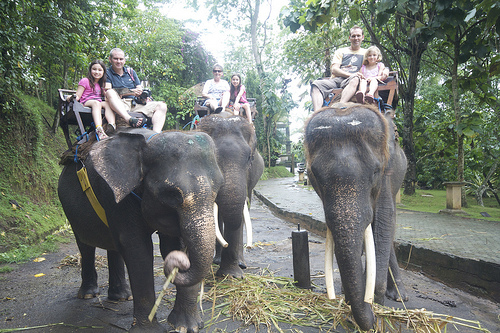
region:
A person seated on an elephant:
[75, 56, 109, 128]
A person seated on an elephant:
[97, 48, 168, 130]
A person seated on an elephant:
[197, 52, 232, 110]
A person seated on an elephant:
[231, 74, 257, 129]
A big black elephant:
[18, 106, 214, 313]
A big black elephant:
[302, 93, 407, 319]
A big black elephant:
[200, 113, 279, 273]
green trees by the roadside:
[375, 0, 498, 170]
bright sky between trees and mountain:
[152, 5, 327, 171]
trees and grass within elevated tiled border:
[260, 10, 495, 270]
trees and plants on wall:
[5, 5, 290, 251]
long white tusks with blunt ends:
[317, 215, 377, 305]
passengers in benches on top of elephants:
[55, 21, 407, 321]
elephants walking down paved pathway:
[17, 17, 482, 327]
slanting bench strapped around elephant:
[51, 41, 166, 226]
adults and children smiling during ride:
[197, 21, 394, 308]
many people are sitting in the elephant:
[36, 12, 446, 329]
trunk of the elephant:
[174, 217, 211, 300]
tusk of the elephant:
[361, 227, 381, 308]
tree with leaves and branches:
[245, 36, 285, 161]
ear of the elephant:
[91, 128, 148, 201]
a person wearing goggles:
[208, 65, 222, 75]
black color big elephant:
[303, 105, 413, 307]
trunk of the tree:
[401, 53, 421, 168]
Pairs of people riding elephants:
[42, 28, 429, 330]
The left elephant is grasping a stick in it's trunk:
[143, 246, 228, 323]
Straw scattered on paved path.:
[201, 271, 473, 332]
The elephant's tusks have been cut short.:
[318, 222, 382, 309]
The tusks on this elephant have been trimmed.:
[207, 197, 259, 253]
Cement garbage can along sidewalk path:
[441, 176, 464, 211]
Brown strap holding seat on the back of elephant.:
[68, 153, 115, 229]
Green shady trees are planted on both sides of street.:
[1, 1, 498, 196]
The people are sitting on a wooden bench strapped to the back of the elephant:
[52, 45, 167, 144]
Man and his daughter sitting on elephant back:
[308, 23, 404, 118]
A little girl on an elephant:
[365, 45, 388, 91]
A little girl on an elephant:
[229, 71, 256, 108]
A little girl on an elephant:
[72, 59, 104, 137]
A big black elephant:
[199, 123, 283, 278]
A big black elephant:
[40, 149, 235, 323]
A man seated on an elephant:
[337, 4, 362, 95]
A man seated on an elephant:
[195, 56, 225, 111]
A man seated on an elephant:
[111, 45, 173, 112]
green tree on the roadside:
[395, 1, 472, 166]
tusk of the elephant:
[353, 220, 386, 302]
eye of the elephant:
[367, 152, 384, 183]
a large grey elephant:
[288, 98, 430, 325]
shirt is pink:
[77, 78, 103, 104]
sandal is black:
[130, 114, 150, 132]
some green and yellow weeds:
[211, 259, 384, 331]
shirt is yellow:
[328, 50, 378, 83]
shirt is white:
[201, 80, 236, 99]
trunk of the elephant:
[137, 210, 234, 299]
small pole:
[286, 221, 315, 293]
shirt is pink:
[360, 61, 381, 81]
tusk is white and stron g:
[357, 224, 385, 301]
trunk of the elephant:
[152, 207, 237, 287]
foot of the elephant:
[165, 295, 203, 329]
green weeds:
[198, 269, 333, 331]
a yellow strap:
[63, 154, 125, 240]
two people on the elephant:
[194, 57, 256, 114]